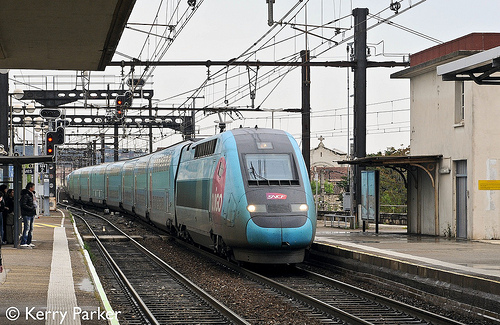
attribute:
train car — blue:
[179, 105, 324, 272]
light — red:
[40, 133, 61, 152]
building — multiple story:
[390, 32, 499, 239]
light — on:
[296, 199, 311, 214]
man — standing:
[17, 183, 44, 248]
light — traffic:
[44, 129, 59, 156]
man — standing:
[20, 181, 34, 248]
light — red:
[114, 97, 125, 107]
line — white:
[39, 200, 88, 320]